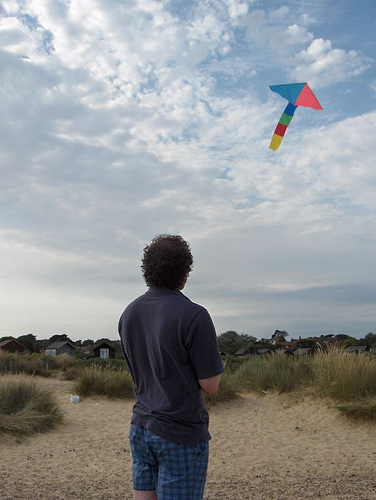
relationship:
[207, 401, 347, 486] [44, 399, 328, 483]
sand on ground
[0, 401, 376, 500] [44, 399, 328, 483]
sand on ground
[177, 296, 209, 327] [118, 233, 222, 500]
shoulder of man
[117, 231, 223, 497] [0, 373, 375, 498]
man standing on sand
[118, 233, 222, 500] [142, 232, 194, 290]
man has curly hair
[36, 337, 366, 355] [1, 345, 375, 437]
huts behind grass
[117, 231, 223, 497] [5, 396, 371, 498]
man on sand